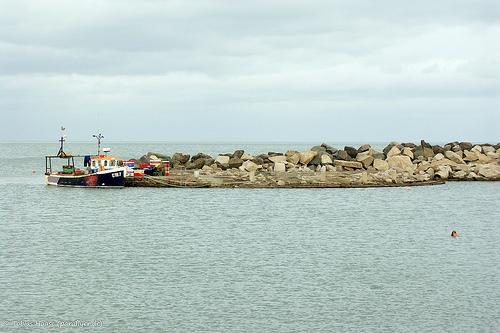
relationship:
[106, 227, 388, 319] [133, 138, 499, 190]
water on one side of island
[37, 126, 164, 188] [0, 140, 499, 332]
boat in water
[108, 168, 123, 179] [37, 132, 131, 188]
letters on side of boat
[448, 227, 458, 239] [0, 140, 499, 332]
object in water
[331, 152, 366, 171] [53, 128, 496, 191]
rock on land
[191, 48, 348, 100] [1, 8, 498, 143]
clouds in sky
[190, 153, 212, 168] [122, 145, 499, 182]
rock on land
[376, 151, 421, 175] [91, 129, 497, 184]
rock on land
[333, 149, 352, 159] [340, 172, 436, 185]
gray rock on land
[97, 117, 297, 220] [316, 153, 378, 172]
rock next to rock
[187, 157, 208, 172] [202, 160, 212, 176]
rock next to rock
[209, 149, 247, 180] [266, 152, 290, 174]
rock next to rock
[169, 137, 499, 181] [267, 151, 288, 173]
rock next to rock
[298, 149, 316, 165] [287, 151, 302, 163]
rock next to rock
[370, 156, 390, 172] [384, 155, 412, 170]
rock next to rock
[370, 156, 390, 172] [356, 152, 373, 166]
rock next to rock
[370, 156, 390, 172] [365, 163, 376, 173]
rock next to rock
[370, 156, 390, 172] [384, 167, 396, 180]
rock next to rock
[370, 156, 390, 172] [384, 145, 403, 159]
rock next to rock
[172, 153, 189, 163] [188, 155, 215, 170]
rock next to rock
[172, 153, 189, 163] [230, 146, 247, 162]
rock next to rock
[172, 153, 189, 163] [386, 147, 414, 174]
rock next to rock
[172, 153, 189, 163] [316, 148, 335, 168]
rock next to rock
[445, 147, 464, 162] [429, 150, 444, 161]
rock next to rock